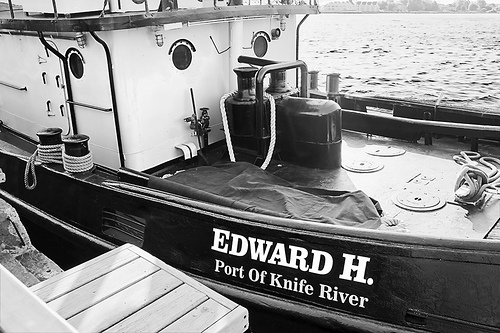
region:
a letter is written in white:
[208, 223, 229, 253]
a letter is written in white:
[228, 227, 247, 258]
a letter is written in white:
[245, 234, 269, 266]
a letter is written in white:
[268, 238, 289, 270]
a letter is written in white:
[248, 265, 259, 285]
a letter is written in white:
[285, 242, 305, 272]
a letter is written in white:
[303, 246, 333, 281]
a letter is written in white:
[332, 245, 368, 286]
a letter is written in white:
[211, 256, 221, 274]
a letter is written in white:
[269, 269, 285, 296]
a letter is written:
[211, 226, 229, 250]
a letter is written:
[226, 227, 248, 259]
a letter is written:
[248, 235, 271, 264]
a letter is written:
[267, 245, 284, 265]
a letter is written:
[281, 240, 306, 271]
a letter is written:
[308, 242, 335, 275]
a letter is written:
[336, 253, 371, 286]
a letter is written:
[210, 257, 223, 277]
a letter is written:
[248, 265, 260, 283]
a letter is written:
[261, 268, 283, 293]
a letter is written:
[268, 235, 289, 262]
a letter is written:
[316, 283, 331, 300]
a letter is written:
[216, 255, 224, 275]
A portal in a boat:
[165, 36, 198, 71]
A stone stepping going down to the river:
[2, 181, 84, 293]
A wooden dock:
[13, 240, 264, 329]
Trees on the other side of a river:
[386, 0, 493, 14]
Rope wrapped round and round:
[16, 131, 105, 190]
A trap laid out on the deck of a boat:
[154, 151, 396, 225]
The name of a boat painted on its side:
[110, 163, 493, 322]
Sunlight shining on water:
[313, 15, 421, 60]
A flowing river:
[313, 13, 480, 69]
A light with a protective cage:
[149, 14, 171, 51]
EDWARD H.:
[205, 226, 377, 289]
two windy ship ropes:
[17, 146, 96, 195]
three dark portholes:
[58, 29, 273, 83]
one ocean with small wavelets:
[251, 5, 496, 111]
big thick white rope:
[213, 85, 280, 181]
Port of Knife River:
[210, 256, 366, 317]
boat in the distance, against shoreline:
[312, 0, 383, 16]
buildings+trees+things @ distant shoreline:
[371, 0, 497, 16]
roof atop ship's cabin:
[0, 0, 323, 40]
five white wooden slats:
[20, 236, 262, 332]